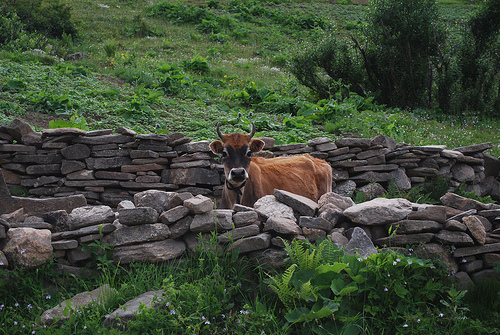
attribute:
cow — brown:
[209, 123, 332, 207]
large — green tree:
[353, 1, 436, 106]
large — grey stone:
[340, 195, 412, 232]